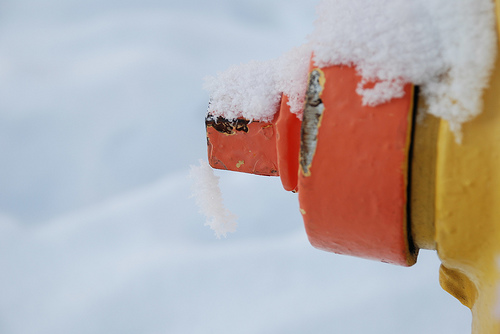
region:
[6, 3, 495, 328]
extended part of fire hydrant in winter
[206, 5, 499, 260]
loose flakes of snow piled on top of hydrant segments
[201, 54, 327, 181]
worn and peeled surfaces of painted hydrant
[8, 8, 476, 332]
curved white edges of snow behind hydrant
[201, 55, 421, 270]
orange screw attached to orange fitting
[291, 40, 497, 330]
orange fitting attached to hydrant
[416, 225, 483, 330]
curves along edge of hydrant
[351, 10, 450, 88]
textured triangle of snow on hydrant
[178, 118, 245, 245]
interconnected flakes of snow hanging from screw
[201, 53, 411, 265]
angled hydrant piece over smooth piece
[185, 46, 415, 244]
red cap of hydrant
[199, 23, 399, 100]
snow covering red cap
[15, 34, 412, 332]
whote snow below hydrant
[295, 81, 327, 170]
paint chips on hydrant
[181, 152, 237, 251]
snow hanging from hydrant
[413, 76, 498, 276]
yellow body of hydrant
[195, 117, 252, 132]
rust on end of hydrant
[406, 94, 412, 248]
metal threads on hydrant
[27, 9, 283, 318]
thick snow covering ground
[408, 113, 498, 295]
water inside fire hydrant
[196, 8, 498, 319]
snow on the fire hydrant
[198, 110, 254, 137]
black rust on the hydrant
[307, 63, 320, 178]
white rust on the hydrant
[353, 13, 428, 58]
white fluffy wet snow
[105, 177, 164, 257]
snow on the ground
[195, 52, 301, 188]
tip of the hydrant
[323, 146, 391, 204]
orange on the hydrant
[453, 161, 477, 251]
yellow on the hydrant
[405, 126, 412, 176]
black hole in the hydrant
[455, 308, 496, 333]
bottom of the hydrant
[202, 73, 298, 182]
PART OF FIRE HYDRANT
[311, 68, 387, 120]
PART OF FIRE HYDRANT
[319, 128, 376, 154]
PART OF FIRE HYDRANT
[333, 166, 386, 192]
PART OF FIRE HYDRANT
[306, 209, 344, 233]
PART OF FIRE HYDRANT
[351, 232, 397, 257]
PART OF FIRE HYDRANT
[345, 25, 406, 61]
SNOW COVERING FIRE HYDRANT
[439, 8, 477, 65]
SNOW COVERING FIRE HYDRANT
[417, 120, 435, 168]
PART OF FIRE HYDRANT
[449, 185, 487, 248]
PART OF FIRE HYDRANT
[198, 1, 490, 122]
snow on top of fire hydrant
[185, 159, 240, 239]
snow dangling off edge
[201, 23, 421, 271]
orange cap on fire hydrant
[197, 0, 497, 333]
yellow and orange fire hydrant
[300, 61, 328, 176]
chipped paint area of fire hydrant cap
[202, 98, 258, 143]
chipped paint under snow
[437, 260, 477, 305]
dirty corner of hydrant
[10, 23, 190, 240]
patch of snow behind hydrant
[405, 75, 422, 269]
seam line where cap meets hydrant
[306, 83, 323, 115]
brown speckle under paint